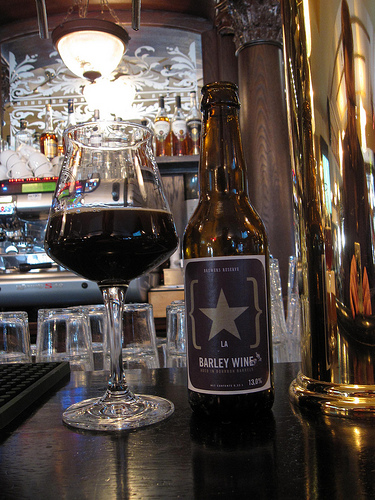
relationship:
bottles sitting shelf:
[13, 89, 203, 157] [152, 153, 199, 174]